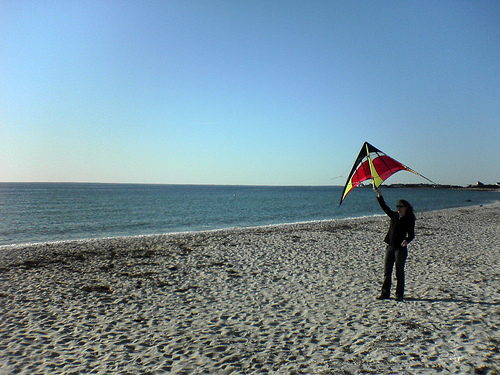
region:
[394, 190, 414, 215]
head of a person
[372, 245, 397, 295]
leg of a person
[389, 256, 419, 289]
leg of a person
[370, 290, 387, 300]
feet of a person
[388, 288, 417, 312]
feet of a person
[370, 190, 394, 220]
arm of a person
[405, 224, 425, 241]
arm of a person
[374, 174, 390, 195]
hand of a person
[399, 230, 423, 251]
hand of a person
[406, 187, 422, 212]
hair of a person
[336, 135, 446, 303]
a woman with a kite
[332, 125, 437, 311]
a woman holding a kite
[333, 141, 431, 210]
a pink purple and yellow kite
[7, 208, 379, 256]
a ocean shore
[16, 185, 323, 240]
crystal clear ocean water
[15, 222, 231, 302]
dark sea weed on a beach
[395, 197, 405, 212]
a woman with sunglasses on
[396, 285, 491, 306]
a shadow in the sand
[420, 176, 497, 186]
a tree shore line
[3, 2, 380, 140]
a crystal clear sky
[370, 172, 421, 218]
arm of a person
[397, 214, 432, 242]
arm of a person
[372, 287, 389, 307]
feet of a person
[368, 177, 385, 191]
hand of a person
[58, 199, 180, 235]
body of clear water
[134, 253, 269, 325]
sand on a beach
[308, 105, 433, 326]
the woman is holding a kite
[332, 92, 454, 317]
a lady holding a kite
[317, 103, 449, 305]
lady holding a kite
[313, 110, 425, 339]
woman standing on sand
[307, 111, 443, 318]
woman at the beach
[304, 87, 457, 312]
a woman flying a kite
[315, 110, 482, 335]
she is lifting the kite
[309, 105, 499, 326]
the kite is lifted above her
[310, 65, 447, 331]
the kite is lifted above her head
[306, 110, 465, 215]
the kite is black, yellow, and red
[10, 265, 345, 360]
The sand on the beach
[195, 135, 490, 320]
Woman on the beach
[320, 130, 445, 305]
Woman holding a kite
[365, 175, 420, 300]
Woman wearing dark attire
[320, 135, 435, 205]
A kite ready to fly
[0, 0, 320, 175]
Sunny blue sky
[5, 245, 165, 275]
A couple of seaweed on the beach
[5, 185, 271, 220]
The blue calming ocean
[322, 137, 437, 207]
The Tri color kite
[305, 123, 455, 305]
Woman ready to play